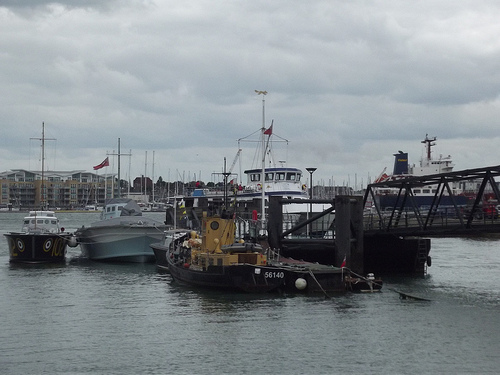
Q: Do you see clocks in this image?
A: No, there are no clocks.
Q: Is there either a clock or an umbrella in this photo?
A: No, there are no clocks or umbrellas.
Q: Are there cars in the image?
A: No, there are no cars.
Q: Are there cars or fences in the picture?
A: No, there are no cars or fences.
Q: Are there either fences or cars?
A: No, there are no cars or fences.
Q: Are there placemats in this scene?
A: No, there are no placemats.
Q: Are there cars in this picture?
A: No, there are no cars.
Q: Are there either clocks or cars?
A: No, there are no cars or clocks.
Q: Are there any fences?
A: No, there are no fences.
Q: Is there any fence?
A: No, there are no fences.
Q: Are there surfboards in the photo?
A: No, there are no surfboards.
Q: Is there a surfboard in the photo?
A: No, there are no surfboards.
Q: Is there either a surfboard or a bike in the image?
A: No, there are no surfboards or bikes.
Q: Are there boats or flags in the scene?
A: Yes, there is a boat.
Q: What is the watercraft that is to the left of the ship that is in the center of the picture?
A: The watercraft is a boat.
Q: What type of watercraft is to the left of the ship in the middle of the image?
A: The watercraft is a boat.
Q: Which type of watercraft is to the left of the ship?
A: The watercraft is a boat.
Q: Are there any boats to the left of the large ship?
A: Yes, there is a boat to the left of the ship.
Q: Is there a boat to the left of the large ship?
A: Yes, there is a boat to the left of the ship.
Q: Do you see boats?
A: Yes, there is a boat.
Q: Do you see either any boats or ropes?
A: Yes, there is a boat.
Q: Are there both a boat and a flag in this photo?
A: Yes, there are both a boat and a flag.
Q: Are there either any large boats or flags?
A: Yes, there is a large boat.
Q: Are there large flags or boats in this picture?
A: Yes, there is a large boat.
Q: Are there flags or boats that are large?
A: Yes, the boat is large.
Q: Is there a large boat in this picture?
A: Yes, there is a large boat.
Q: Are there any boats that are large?
A: Yes, there is a boat that is large.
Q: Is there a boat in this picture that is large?
A: Yes, there is a boat that is large.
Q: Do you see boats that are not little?
A: Yes, there is a large boat.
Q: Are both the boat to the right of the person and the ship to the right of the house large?
A: Yes, both the boat and the ship are large.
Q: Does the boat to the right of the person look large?
A: Yes, the boat is large.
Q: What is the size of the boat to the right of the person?
A: The boat is large.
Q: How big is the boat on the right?
A: The boat is large.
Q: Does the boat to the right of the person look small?
A: No, the boat is large.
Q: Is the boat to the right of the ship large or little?
A: The boat is large.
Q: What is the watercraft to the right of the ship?
A: The watercraft is a boat.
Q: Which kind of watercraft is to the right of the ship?
A: The watercraft is a boat.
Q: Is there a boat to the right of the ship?
A: Yes, there is a boat to the right of the ship.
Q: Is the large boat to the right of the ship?
A: Yes, the boat is to the right of the ship.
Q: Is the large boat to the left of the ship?
A: No, the boat is to the right of the ship.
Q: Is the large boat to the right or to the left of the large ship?
A: The boat is to the right of the ship.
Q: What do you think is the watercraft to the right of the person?
A: The watercraft is a boat.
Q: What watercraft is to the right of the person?
A: The watercraft is a boat.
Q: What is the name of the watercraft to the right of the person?
A: The watercraft is a boat.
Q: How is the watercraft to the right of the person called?
A: The watercraft is a boat.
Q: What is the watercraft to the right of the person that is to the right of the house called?
A: The watercraft is a boat.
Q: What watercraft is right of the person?
A: The watercraft is a boat.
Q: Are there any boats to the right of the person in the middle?
A: Yes, there is a boat to the right of the person.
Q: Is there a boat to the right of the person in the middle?
A: Yes, there is a boat to the right of the person.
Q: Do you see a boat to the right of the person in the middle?
A: Yes, there is a boat to the right of the person.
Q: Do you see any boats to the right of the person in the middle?
A: Yes, there is a boat to the right of the person.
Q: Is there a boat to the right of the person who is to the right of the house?
A: Yes, there is a boat to the right of the person.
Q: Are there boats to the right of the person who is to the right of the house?
A: Yes, there is a boat to the right of the person.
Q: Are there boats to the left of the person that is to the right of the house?
A: No, the boat is to the right of the person.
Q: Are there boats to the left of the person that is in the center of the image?
A: No, the boat is to the right of the person.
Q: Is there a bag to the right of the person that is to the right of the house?
A: No, there is a boat to the right of the person.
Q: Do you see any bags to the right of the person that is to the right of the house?
A: No, there is a boat to the right of the person.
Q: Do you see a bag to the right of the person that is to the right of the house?
A: No, there is a boat to the right of the person.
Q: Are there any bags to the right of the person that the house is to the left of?
A: No, there is a boat to the right of the person.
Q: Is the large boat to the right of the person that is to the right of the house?
A: Yes, the boat is to the right of the person.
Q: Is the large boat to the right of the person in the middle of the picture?
A: Yes, the boat is to the right of the person.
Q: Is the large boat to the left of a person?
A: No, the boat is to the right of a person.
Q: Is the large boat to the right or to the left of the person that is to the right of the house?
A: The boat is to the right of the person.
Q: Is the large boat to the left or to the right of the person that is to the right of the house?
A: The boat is to the right of the person.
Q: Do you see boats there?
A: Yes, there is a boat.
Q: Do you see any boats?
A: Yes, there is a boat.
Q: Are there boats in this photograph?
A: Yes, there is a boat.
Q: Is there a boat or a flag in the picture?
A: Yes, there is a boat.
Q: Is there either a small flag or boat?
A: Yes, there is a small boat.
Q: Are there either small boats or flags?
A: Yes, there is a small boat.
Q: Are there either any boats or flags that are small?
A: Yes, the boat is small.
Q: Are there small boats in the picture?
A: Yes, there is a small boat.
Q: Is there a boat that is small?
A: Yes, there is a boat that is small.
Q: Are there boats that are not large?
A: Yes, there is a small boat.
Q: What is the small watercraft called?
A: The watercraft is a boat.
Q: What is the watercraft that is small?
A: The watercraft is a boat.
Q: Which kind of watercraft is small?
A: The watercraft is a boat.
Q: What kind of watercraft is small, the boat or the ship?
A: The boat is small.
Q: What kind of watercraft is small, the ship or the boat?
A: The boat is small.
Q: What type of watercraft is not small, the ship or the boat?
A: The ship is not small.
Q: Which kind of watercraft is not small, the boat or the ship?
A: The ship is not small.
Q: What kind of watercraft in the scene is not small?
A: The watercraft is a ship.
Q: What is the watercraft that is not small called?
A: The watercraft is a ship.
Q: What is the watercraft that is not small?
A: The watercraft is a ship.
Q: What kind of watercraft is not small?
A: The watercraft is a ship.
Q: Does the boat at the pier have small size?
A: Yes, the boat is small.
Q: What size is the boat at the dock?
A: The boat is small.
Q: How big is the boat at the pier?
A: The boat is small.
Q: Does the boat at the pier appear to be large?
A: No, the boat is small.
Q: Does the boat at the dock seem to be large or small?
A: The boat is small.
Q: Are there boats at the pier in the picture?
A: Yes, there is a boat at the pier.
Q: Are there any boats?
A: Yes, there is a boat.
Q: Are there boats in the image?
A: Yes, there is a boat.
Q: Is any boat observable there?
A: Yes, there is a boat.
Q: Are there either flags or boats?
A: Yes, there is a boat.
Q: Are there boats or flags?
A: Yes, there is a boat.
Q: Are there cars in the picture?
A: No, there are no cars.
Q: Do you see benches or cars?
A: No, there are no cars or benches.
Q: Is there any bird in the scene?
A: No, there are no birds.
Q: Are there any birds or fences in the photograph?
A: No, there are no birds or fences.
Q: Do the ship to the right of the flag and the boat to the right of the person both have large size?
A: Yes, both the ship and the boat are large.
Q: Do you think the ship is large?
A: Yes, the ship is large.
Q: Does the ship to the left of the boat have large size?
A: Yes, the ship is large.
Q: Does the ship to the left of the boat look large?
A: Yes, the ship is large.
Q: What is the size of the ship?
A: The ship is large.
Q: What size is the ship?
A: The ship is large.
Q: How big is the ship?
A: The ship is large.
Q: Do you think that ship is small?
A: No, the ship is large.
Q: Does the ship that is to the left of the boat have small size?
A: No, the ship is large.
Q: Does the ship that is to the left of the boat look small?
A: No, the ship is large.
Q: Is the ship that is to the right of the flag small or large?
A: The ship is large.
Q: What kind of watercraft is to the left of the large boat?
A: The watercraft is a ship.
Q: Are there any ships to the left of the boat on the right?
A: Yes, there is a ship to the left of the boat.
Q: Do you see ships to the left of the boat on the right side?
A: Yes, there is a ship to the left of the boat.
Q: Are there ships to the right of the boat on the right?
A: No, the ship is to the left of the boat.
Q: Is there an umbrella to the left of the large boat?
A: No, there is a ship to the left of the boat.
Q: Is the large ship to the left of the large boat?
A: Yes, the ship is to the left of the boat.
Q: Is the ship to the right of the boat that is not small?
A: No, the ship is to the left of the boat.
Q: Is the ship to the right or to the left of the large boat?
A: The ship is to the left of the boat.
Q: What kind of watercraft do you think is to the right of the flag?
A: The watercraft is a ship.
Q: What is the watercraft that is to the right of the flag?
A: The watercraft is a ship.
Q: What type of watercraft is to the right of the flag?
A: The watercraft is a ship.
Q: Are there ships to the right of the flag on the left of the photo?
A: Yes, there is a ship to the right of the flag.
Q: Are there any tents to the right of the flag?
A: No, there is a ship to the right of the flag.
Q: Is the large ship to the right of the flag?
A: Yes, the ship is to the right of the flag.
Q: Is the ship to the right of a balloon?
A: No, the ship is to the right of the flag.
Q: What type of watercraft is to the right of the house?
A: The watercraft is a ship.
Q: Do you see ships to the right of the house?
A: Yes, there is a ship to the right of the house.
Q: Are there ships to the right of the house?
A: Yes, there is a ship to the right of the house.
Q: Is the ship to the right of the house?
A: Yes, the ship is to the right of the house.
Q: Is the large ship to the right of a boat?
A: Yes, the ship is to the right of a boat.